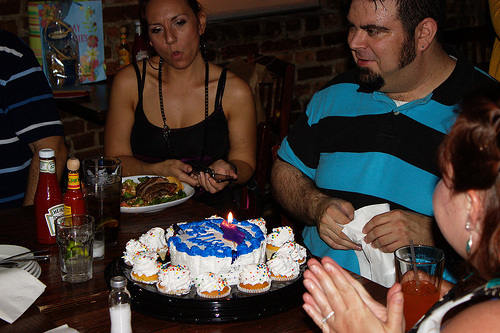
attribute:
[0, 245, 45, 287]
white plates —  white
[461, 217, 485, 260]
earring — silver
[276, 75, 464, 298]
shirt — black,blue and striped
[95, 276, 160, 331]
shaker — clear, gray and white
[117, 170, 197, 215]
plate — untouched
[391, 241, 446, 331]
glass — half full, half-full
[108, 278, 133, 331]
salt shaker — half-full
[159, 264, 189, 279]
sprinkles — multi colored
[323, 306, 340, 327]
ring — silver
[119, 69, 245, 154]
top — black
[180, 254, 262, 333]
frosting —  white